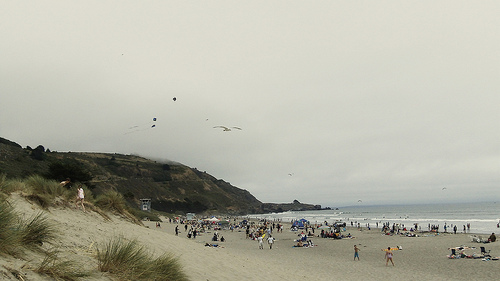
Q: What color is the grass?
A: Green.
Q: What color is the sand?
A: Tan.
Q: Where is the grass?
A: In the sand.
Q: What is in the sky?
A: The bird.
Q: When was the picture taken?
A: Daytime.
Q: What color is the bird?
A: White.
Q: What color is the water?
A: Blue and white.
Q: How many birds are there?
A: One.